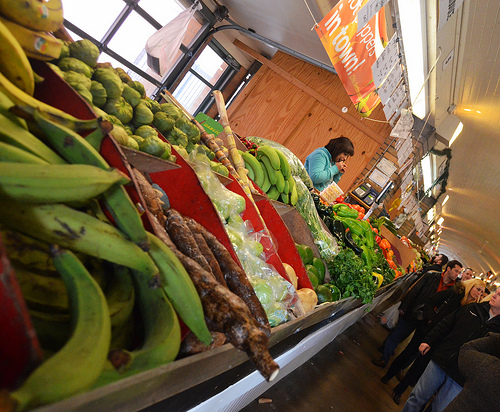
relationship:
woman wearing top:
[302, 135, 356, 192] [306, 147, 341, 192]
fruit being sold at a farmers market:
[230, 144, 297, 206] [1, 1, 454, 409]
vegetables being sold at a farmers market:
[296, 205, 404, 304] [1, 1, 454, 409]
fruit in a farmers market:
[52, 37, 230, 178] [1, 0, 500, 412]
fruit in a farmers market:
[230, 144, 297, 206] [1, 0, 500, 412]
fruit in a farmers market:
[294, 241, 343, 307] [1, 0, 500, 412]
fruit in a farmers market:
[0, 1, 212, 411] [1, 0, 500, 412]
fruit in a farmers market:
[190, 164, 296, 326] [1, 0, 500, 412]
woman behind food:
[275, 132, 373, 212] [21, 84, 209, 397]